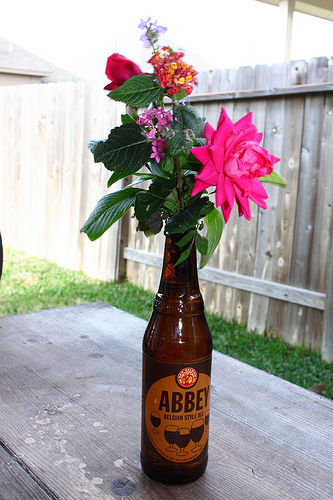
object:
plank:
[198, 55, 333, 105]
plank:
[55, 89, 91, 261]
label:
[144, 367, 210, 464]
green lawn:
[0, 249, 91, 305]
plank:
[245, 56, 332, 345]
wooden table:
[0, 306, 333, 499]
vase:
[140, 229, 214, 488]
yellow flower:
[171, 62, 177, 69]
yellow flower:
[179, 77, 186, 82]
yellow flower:
[186, 76, 192, 80]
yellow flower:
[181, 62, 186, 70]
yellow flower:
[155, 55, 159, 61]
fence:
[234, 235, 323, 301]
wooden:
[257, 210, 315, 260]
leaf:
[86, 113, 152, 191]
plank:
[6, 78, 58, 250]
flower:
[136, 107, 173, 164]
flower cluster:
[79, 10, 287, 272]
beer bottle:
[141, 230, 214, 486]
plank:
[118, 246, 332, 351]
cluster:
[78, 15, 287, 272]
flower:
[187, 106, 281, 225]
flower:
[147, 47, 199, 95]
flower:
[137, 16, 169, 50]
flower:
[103, 52, 149, 92]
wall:
[0, 40, 333, 297]